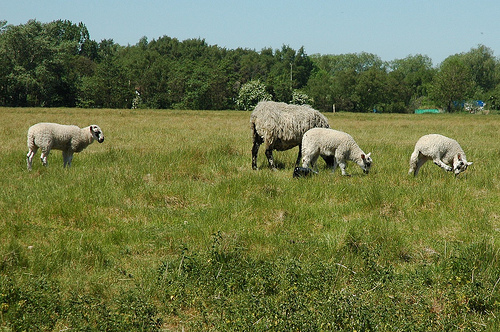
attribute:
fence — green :
[408, 101, 449, 115]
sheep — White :
[407, 130, 474, 181]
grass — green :
[163, 177, 313, 277]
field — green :
[121, 128, 247, 245]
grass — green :
[203, 225, 270, 289]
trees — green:
[440, 47, 497, 113]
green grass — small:
[0, 105, 498, 327]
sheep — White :
[26, 119, 106, 170]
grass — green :
[0, 102, 496, 329]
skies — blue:
[227, 12, 368, 41]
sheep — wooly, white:
[24, 123, 107, 168]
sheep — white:
[300, 128, 372, 175]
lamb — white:
[388, 112, 496, 201]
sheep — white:
[297, 124, 375, 181]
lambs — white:
[19, 91, 477, 199]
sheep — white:
[29, 121, 497, 186]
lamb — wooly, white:
[388, 117, 482, 182]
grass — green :
[198, 217, 275, 292]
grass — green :
[318, 207, 473, 242]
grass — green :
[167, 180, 427, 303]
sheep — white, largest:
[251, 97, 330, 173]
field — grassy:
[0, 173, 464, 329]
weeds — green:
[2, 171, 484, 330]